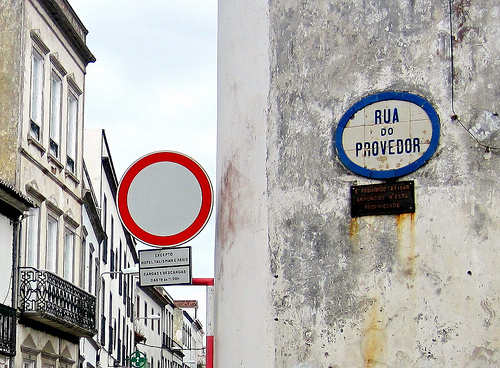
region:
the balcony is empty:
[20, 259, 107, 334]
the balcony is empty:
[13, 236, 123, 333]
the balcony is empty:
[11, 252, 116, 346]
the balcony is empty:
[14, 245, 113, 331]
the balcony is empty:
[3, 251, 114, 338]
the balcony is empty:
[14, 253, 131, 341]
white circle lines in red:
[115, 150, 212, 250]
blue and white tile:
[335, 87, 442, 177]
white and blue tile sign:
[334, 88, 440, 179]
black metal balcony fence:
[15, 262, 97, 339]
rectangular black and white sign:
[132, 243, 195, 288]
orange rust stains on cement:
[343, 210, 418, 367]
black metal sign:
[347, 178, 416, 220]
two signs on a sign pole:
[114, 145, 218, 366]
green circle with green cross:
[122, 348, 147, 367]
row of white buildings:
[1, 0, 203, 367]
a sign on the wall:
[324, 82, 441, 198]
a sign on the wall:
[317, 67, 446, 192]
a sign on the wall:
[317, 79, 424, 167]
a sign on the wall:
[336, 87, 453, 202]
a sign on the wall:
[324, 90, 451, 198]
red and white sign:
[117, 164, 206, 249]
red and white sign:
[101, 133, 220, 271]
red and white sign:
[111, 142, 222, 266]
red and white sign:
[104, 142, 225, 262]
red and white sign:
[89, 126, 215, 263]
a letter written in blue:
[352, 142, 363, 162]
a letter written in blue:
[363, 138, 374, 163]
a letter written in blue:
[371, 138, 384, 163]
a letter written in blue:
[380, 138, 395, 160]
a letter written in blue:
[385, 138, 400, 160]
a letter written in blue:
[393, 136, 409, 157]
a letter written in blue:
[405, 138, 420, 161]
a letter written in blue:
[370, 111, 384, 130]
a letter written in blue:
[392, 108, 404, 121]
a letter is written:
[373, 106, 381, 123]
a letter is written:
[381, 103, 388, 128]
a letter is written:
[390, 107, 404, 129]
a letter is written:
[379, 123, 385, 144]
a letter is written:
[385, 126, 393, 138]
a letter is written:
[413, 132, 423, 156]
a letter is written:
[395, 135, 408, 173]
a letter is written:
[404, 135, 411, 157]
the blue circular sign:
[323, 78, 445, 176]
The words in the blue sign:
[356, 109, 426, 162]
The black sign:
[344, 176, 421, 226]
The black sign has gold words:
[354, 184, 417, 214]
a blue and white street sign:
[327, 84, 446, 184]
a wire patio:
[7, 245, 122, 335]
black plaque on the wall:
[346, 183, 411, 215]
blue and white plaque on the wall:
[317, 86, 447, 177]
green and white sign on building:
[124, 349, 150, 365]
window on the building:
[24, 43, 46, 144]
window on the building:
[45, 57, 63, 161]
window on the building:
[63, 74, 83, 179]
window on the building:
[21, 191, 43, 271]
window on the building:
[41, 206, 61, 275]